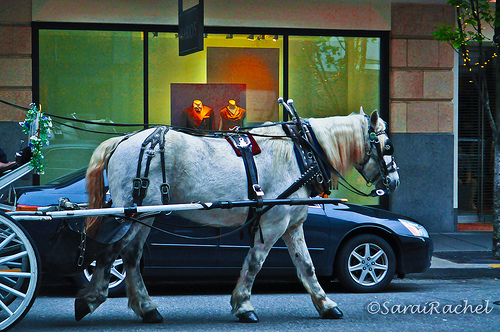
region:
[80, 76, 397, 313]
a white horse on the street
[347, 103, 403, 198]
the head of a horse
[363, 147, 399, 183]
a black leather horse bridle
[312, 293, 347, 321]
the hoof of a horse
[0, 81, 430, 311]
a horse pulling a carriage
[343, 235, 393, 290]
the front wheel of a vehicle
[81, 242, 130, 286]
the rear wheel of a vehicle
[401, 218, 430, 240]
the headlight of a vehicle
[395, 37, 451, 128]
the stone front of a building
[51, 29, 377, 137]
glass window of a storefront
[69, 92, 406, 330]
a white horse walking in the street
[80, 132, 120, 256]
tail of horse is white and brown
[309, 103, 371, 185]
mane of horse is white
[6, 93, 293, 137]
black rains tied to horse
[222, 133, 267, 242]
girth pass under the belly of horse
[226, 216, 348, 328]
front legs of horse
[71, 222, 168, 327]
back legs of horse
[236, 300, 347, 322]
hooves of horse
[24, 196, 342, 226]
tug of horse is long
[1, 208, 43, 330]
the wheel of a cart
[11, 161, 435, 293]
black car by curb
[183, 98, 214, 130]
manniquin in store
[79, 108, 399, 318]
white and brown horse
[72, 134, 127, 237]
brown and white horses tail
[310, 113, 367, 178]
white and brown mane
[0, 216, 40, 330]
black and white carriage wheel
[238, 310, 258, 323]
black hoof on horse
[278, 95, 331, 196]
black harness on horse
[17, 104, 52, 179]
blue flowers on carriage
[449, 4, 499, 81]
christmas lights in tree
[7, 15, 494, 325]
horse and wagon on street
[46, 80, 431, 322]
horse is white and brown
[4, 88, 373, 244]
horse wearing black leads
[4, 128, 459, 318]
car parked next to horse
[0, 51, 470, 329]
horse and car in front of storefront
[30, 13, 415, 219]
green wall inside store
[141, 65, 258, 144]
two mannequins inside store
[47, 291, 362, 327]
black feet on horse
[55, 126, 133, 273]
white and brown tail on horse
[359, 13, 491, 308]
brick on building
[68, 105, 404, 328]
Horse with a lot of harness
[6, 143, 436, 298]
Parked shiny dark car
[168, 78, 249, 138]
Painting of two headless persons in red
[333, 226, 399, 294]
Round wheel of a car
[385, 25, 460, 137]
Bricks of a wall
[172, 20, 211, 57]
Sign on the roof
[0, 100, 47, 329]
Front part of a chariot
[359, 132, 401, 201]
Bridle on a horse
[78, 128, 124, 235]
Bushy thick white tail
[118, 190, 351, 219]
Chariot strapping on a horse